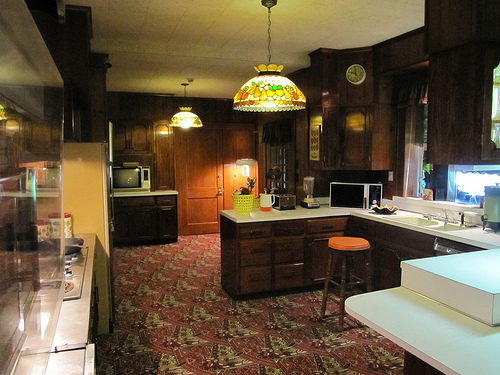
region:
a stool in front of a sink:
[309, 230, 389, 326]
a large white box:
[397, 237, 499, 333]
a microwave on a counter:
[325, 176, 387, 211]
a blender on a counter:
[297, 173, 321, 214]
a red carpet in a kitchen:
[111, 228, 404, 374]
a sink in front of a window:
[383, 202, 473, 238]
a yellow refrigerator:
[66, 139, 121, 344]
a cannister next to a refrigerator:
[56, 204, 80, 242]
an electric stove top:
[55, 239, 92, 309]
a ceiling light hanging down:
[229, 61, 314, 121]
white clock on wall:
[337, 59, 371, 90]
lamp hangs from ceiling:
[224, 1, 311, 121]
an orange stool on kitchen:
[316, 219, 378, 328]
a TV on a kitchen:
[111, 159, 157, 196]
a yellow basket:
[226, 187, 256, 217]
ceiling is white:
[105, 5, 391, 50]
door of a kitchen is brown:
[171, 125, 230, 234]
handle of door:
[214, 181, 228, 201]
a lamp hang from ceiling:
[164, 76, 207, 136]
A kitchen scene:
[23, 37, 486, 366]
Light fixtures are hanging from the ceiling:
[154, 0, 314, 132]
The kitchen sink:
[389, 197, 474, 234]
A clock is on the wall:
[339, 57, 374, 89]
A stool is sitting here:
[311, 232, 376, 331]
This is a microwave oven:
[320, 175, 394, 212]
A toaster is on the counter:
[271, 184, 299, 213]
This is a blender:
[298, 171, 324, 213]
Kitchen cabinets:
[317, 102, 382, 171]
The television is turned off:
[112, 159, 152, 201]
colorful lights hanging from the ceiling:
[167, 1, 307, 132]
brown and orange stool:
[314, 233, 374, 333]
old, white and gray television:
[110, 162, 155, 192]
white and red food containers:
[31, 209, 74, 241]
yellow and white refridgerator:
[61, 136, 118, 341]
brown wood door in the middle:
[174, 122, 227, 239]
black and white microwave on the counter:
[321, 176, 388, 213]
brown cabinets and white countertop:
[221, 205, 352, 301]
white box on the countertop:
[393, 241, 498, 328]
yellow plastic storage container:
[230, 179, 256, 219]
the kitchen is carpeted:
[151, 278, 261, 349]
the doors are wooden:
[181, 135, 222, 240]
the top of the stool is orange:
[330, 230, 370, 255]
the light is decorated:
[234, 76, 305, 111]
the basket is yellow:
[227, 189, 260, 219]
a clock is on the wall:
[331, 67, 371, 90]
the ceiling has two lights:
[107, 81, 365, 133]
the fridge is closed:
[79, 146, 136, 337]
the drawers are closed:
[246, 228, 336, 280]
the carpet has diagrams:
[139, 278, 225, 368]